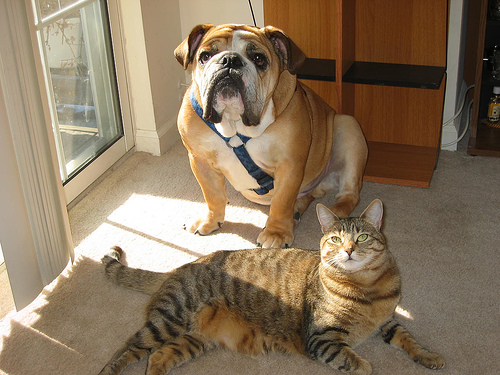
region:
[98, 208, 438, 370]
a cat on the floor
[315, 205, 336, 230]
the right ear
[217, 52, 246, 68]
the bull dogs nose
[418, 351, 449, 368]
the cats paw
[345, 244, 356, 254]
nose of the cat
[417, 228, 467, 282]
the carpet is white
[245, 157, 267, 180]
a strap on the dog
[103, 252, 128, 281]
the cats tail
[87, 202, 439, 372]
the cat is laying down.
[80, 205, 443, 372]
the cat is a gray tabby color.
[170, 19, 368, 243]
the dog is brown and white.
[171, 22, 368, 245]
the dog is sitting up.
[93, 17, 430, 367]
dog and cat next to sliding glass door.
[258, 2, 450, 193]
wooden shelf behind the dog.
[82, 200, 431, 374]
the cat is laying on beige carpet.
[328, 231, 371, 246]
the cat has yellow eyes.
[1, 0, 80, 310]
white vertical blinds on the door.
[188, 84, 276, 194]
dog is wearing black harness.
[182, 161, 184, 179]
A cat and a dog on the carpet.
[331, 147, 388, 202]
the dog is sitting on the shelf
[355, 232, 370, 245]
the cat's eyes are green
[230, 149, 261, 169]
the harness is blue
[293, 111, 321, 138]
the dog is brown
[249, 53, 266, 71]
the eyes are brown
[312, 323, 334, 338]
the stripe is black